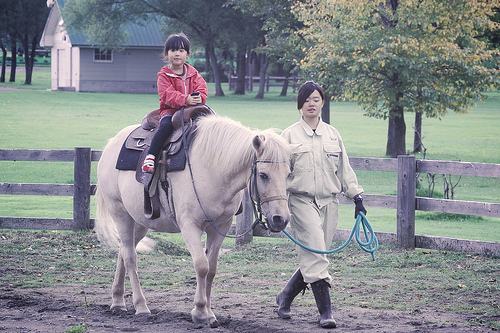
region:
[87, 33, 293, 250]
a child riding a horse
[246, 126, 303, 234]
the head of a horse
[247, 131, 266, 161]
the ear of a horse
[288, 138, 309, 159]
the ear of a horse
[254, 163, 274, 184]
the eye of a horse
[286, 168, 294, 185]
the eye of a horse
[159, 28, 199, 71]
the head of a little girl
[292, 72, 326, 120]
the head of a woman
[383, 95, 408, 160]
a trunk of a tree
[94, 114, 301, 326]
White horse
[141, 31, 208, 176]
Little girl sitting on the horse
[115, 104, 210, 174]
Bridge piece on the horse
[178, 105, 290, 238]
Rein on the horse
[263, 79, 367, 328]
Woman walking by the horse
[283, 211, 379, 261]
Rope in the woman's hands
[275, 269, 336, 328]
Boots on the woman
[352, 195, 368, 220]
Glove on the woman's left hand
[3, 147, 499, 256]
Wood fence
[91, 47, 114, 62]
Window on the house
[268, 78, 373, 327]
Asian woman with dark hair leading horse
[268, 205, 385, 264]
blue rope held by woman leading horse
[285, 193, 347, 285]
khaki pants worn by asian woman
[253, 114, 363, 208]
long sleeve khaki shirt worn by Asian woman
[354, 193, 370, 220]
black gloves worn by Asian woman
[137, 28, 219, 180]
small Asian girl riding horse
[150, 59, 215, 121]
red jacket worn by small girl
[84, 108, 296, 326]
white horse rode by little girl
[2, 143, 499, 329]
land enlcosed by wooden fence for retaining horse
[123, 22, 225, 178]
this is a little girl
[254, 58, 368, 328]
this is a woman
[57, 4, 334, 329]
girl riding a horse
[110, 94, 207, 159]
saddle on a horse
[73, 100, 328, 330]
horse is tan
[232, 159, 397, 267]
this a green lead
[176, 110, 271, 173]
blonde hair on horse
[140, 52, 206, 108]
girl wearing red jacket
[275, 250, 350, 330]
woman wearing black boots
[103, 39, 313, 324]
horse walking in dirt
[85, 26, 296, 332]
A girl is riding on a horse.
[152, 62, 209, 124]
A girl is wearing a red jacket.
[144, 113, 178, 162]
A girl is wearing dark pants.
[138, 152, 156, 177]
A girl is wearing red and white shoes.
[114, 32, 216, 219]
A girl is sitting on a saddle.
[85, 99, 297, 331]
The color of a horse is white.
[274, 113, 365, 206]
A woman is wearing a white shirt.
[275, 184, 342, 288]
A woman is wearing white pants.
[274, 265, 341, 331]
A woman is wearing black boots.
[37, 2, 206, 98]
A house is in the background.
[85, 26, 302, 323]
girl riding white horse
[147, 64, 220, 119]
red rain jacket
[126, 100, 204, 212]
brown horse saddle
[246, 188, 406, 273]
green leash for horse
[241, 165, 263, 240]
black horse bridle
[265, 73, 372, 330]
woman leading horse